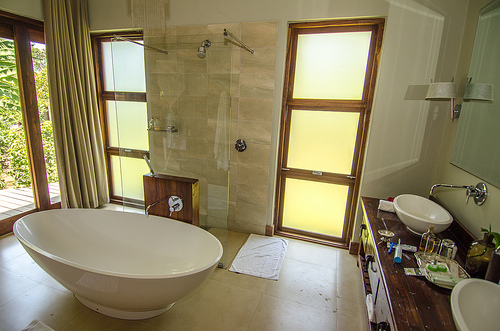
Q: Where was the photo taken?
A: Bathroom.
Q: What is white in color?
A: Tub.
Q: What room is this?
A: Bathroom.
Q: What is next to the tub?
A: Windows.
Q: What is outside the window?
A: Trees.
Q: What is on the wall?
A: Faucet.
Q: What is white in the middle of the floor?
A: A tub.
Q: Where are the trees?
A: To the left.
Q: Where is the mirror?
A: Over the vanity.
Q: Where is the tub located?
A: Center of the bathroom.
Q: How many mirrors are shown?
A: One.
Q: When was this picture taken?
A: During the day.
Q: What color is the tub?
A: White.